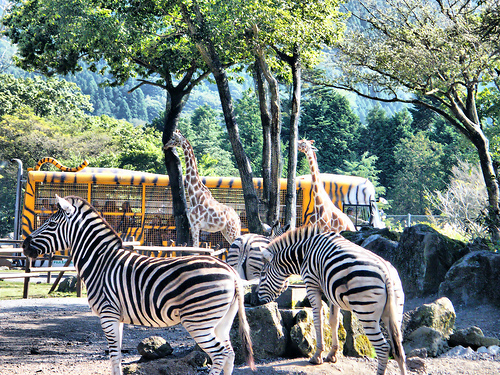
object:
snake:
[24, 156, 92, 172]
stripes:
[86, 173, 149, 188]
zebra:
[22, 193, 235, 371]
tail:
[235, 284, 255, 372]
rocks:
[240, 303, 288, 354]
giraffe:
[300, 135, 358, 235]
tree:
[227, 6, 286, 230]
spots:
[313, 215, 344, 231]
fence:
[29, 260, 88, 295]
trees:
[0, 67, 166, 174]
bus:
[23, 166, 377, 262]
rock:
[134, 333, 172, 359]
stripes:
[32, 197, 225, 374]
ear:
[54, 193, 74, 215]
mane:
[84, 206, 133, 240]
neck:
[307, 151, 322, 198]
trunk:
[173, 243, 194, 252]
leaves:
[0, 46, 500, 86]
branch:
[127, 77, 177, 91]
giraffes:
[165, 132, 241, 254]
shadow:
[0, 301, 212, 374]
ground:
[0, 293, 480, 372]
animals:
[244, 222, 404, 374]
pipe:
[0, 231, 18, 244]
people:
[74, 190, 159, 216]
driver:
[343, 207, 358, 224]